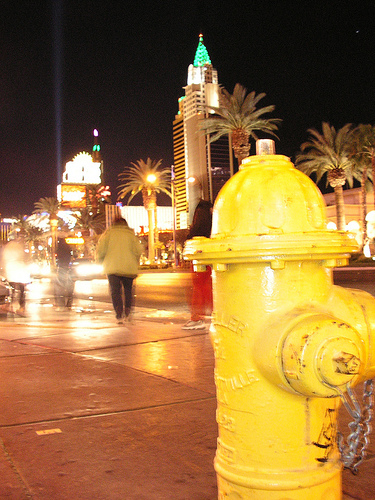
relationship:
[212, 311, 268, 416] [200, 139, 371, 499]
letters on hydrant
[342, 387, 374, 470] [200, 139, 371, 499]
chain on hydrant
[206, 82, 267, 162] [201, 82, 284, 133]
tree has leaves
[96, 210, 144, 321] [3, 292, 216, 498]
person on sidewalk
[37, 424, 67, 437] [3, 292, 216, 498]
paper on sidewalk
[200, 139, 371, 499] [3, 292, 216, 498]
hydrant on sidewalk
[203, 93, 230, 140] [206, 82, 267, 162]
branches on tree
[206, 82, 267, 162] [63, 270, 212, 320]
tree beside road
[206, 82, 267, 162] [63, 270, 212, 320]
tree near road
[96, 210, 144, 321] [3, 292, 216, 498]
woman on sidewalk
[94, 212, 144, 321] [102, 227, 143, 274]
person wears jacket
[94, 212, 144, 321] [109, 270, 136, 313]
person wears pants